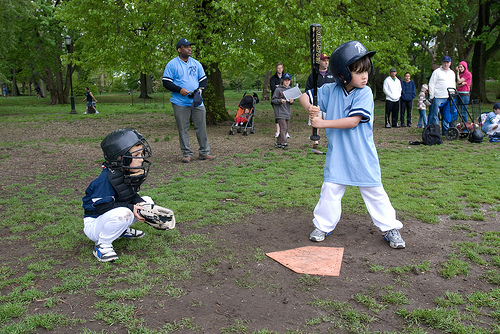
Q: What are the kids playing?
A: Baseball.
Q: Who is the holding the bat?
A: The boy with light blue shirt.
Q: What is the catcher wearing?
A: Dark blue shirt and white pants.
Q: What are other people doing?
A: Watching the game.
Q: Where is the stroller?
A: Near a tree.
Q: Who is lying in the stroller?
A: A small kid.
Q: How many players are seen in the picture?
A: Two.